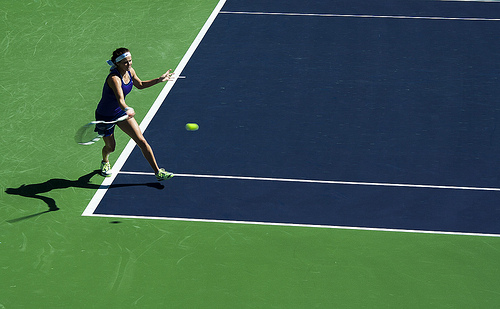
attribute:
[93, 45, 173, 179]
player — playing, woman, hitting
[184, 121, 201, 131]
ball — airborne, yellow, green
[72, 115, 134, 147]
racket — white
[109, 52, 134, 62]
band — white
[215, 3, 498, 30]
line — white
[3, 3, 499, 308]
court — blue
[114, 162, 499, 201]
line — white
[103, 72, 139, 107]
tank — blue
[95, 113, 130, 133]
shorts — blue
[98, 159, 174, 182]
shoes — green